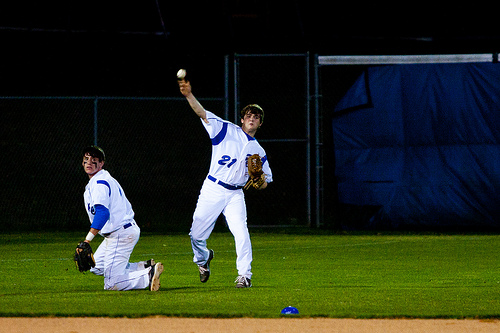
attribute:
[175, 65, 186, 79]
baseball — for baseball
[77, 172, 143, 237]
baseball shirt — white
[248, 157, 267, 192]
catcher mitt — brown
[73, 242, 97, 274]
catcher mitt — brown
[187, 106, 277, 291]
uniform —  white and blue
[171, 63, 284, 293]
baseball player —  for baseball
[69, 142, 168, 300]
player —  for baseball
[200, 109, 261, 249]
uniform — white, blue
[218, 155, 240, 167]
numbers — blue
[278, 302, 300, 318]
helmet — blue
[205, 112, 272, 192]
shirt — man's, white, blue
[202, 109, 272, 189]
shirt — white, baseball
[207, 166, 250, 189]
belt — blue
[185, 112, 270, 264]
uniform —  blue and white,  for baseball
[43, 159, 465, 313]
grass — green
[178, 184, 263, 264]
pants — white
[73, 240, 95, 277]
glove — black,  for baseball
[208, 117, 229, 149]
trim — blue